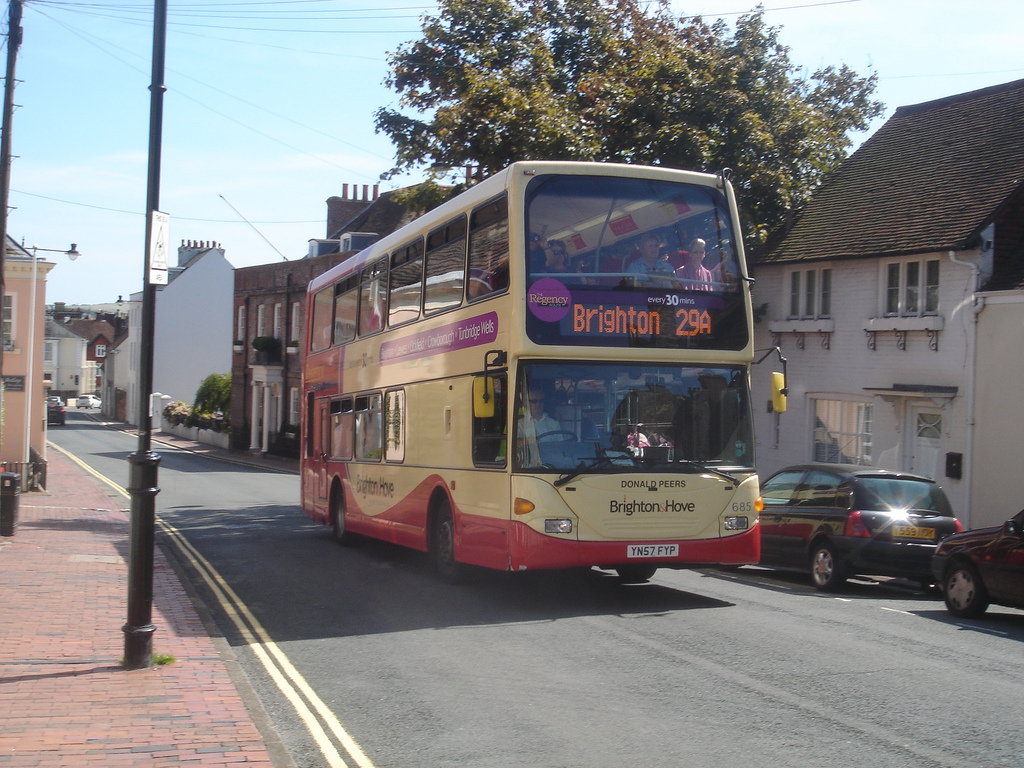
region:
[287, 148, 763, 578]
Large yellow and red bus.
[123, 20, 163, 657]
A tall black street light.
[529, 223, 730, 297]
People sitting on top level.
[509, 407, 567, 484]
Bus driver wearing white shirt.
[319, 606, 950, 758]
Black colored pavement road.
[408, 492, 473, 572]
Front right wheel of bus.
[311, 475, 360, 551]
Right rear wheel of bus.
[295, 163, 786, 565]
Bus driving down street.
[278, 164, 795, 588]
Bus travelling down the road.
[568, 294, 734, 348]
letters on bus are orange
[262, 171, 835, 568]
bus is red and yellow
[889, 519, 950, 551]
license plate on care is yellow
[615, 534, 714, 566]
bus has a license plate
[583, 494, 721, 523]
bus has black letters on it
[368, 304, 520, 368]
bus has purple banner on the side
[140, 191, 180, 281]
pole has white sign on it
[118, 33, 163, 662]
pole with sign is black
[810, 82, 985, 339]
roof of house is brown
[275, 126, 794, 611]
the bus is double-decker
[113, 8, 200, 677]
the pole is black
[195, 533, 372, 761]
the lines are color yellow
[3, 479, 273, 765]
the sidewalk is red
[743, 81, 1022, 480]
the facade is gray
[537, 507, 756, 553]
the headlights of a bus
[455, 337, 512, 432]
the mirror is yellow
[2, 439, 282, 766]
brick side wak next to street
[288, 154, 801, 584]
double decker bus going down the road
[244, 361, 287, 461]
white pillar entry way on a building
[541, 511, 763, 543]
headlights on the front of a bus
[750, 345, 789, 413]
yellow side view mirror on the bus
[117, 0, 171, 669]
metal pole on brick sidewalk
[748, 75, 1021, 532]
white building on right side of the street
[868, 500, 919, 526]
sun glare on black metal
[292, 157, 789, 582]
vehicle for transporting multiple people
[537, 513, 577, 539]
Light on the front of a bus.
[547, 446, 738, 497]
Windshield wipers on a bus.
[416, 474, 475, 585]
Black tire on a bus.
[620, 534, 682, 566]
License plate on a bus.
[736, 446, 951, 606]
Black car by a road.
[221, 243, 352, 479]
Brick building by a road.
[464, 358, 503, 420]
Mirror on a bus.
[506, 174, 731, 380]
Windshield on a bus.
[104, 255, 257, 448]
White building by a street.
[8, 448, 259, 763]
a brick paved sidewalk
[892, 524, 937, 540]
a yellow license plate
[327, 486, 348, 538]
a bus rear tire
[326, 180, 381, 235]
a set of brick chimneys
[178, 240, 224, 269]
a set of brick chimneys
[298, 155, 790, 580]
a double decker bus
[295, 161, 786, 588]
a public service bus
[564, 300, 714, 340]
an electronic bus destination sign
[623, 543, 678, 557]
a bus license plate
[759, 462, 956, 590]
a black parked car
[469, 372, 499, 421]
a bus sideview mirror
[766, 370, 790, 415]
a bus sideview mirror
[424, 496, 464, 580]
a bus front tire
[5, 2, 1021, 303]
a cloudy blue sky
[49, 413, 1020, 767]
a paved city street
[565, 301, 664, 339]
Writing on the front of the bus.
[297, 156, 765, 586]
Bus driving down the road.